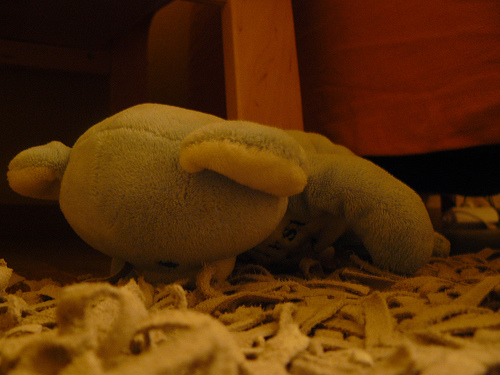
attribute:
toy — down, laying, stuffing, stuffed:
[86, 123, 392, 284]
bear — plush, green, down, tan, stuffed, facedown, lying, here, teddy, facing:
[80, 146, 231, 231]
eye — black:
[160, 255, 179, 272]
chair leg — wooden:
[206, 22, 298, 110]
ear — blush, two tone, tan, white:
[204, 138, 289, 189]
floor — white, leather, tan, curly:
[261, 295, 306, 325]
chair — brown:
[401, 84, 402, 85]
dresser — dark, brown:
[49, 50, 113, 81]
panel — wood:
[77, 5, 160, 87]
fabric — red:
[369, 131, 420, 166]